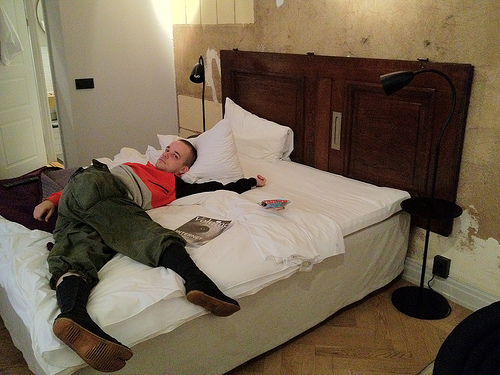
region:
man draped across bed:
[32, 135, 267, 372]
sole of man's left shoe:
[186, 290, 239, 317]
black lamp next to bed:
[187, 51, 207, 133]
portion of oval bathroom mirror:
[34, 0, 46, 35]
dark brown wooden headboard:
[218, 49, 474, 237]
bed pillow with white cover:
[224, 94, 293, 161]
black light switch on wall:
[72, 77, 94, 89]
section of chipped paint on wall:
[457, 201, 479, 249]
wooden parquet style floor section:
[321, 320, 425, 373]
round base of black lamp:
[390, 283, 452, 320]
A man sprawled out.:
[26, 129, 267, 373]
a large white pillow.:
[206, 93, 306, 168]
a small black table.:
[375, 176, 472, 325]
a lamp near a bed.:
[181, 45, 221, 133]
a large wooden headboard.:
[217, 51, 482, 239]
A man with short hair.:
[140, 132, 204, 186]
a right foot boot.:
[51, 293, 146, 373]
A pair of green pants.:
[47, 152, 229, 282]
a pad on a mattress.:
[1, 130, 422, 362]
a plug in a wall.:
[410, 251, 461, 287]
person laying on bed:
[15, 128, 243, 358]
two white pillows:
[162, 105, 295, 185]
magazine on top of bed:
[175, 209, 239, 264]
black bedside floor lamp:
[373, 58, 463, 316]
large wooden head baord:
[188, 44, 485, 178]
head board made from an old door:
[219, 51, 472, 193]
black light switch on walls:
[67, 73, 113, 98]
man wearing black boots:
[60, 245, 236, 364]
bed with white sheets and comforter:
[29, 146, 399, 353]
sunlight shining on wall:
[152, 0, 204, 46]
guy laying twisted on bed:
[21, 122, 324, 373]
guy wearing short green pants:
[27, 114, 258, 291]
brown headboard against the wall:
[182, 20, 478, 277]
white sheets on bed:
[77, 110, 436, 305]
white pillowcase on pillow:
[222, 93, 305, 168]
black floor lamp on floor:
[367, 49, 455, 374]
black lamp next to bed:
[162, 34, 279, 219]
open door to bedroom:
[4, 40, 109, 255]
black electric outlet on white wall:
[415, 231, 495, 284]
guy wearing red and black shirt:
[77, 117, 227, 219]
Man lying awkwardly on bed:
[26, 96, 413, 368]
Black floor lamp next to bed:
[376, 58, 459, 325]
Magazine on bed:
[173, 212, 230, 246]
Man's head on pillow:
[151, 117, 241, 185]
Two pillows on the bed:
[157, 96, 294, 178]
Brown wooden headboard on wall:
[211, 45, 478, 239]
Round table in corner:
[432, 300, 498, 374]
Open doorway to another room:
[30, 0, 70, 163]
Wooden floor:
[232, 277, 489, 374]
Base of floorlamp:
[390, 283, 453, 323]